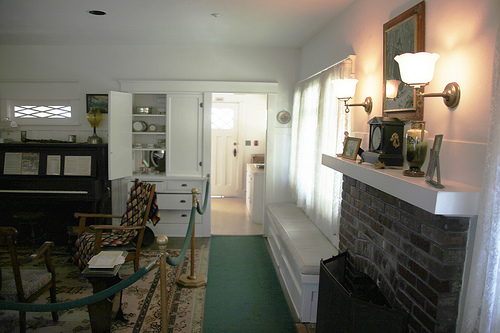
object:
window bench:
[264, 150, 368, 300]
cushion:
[266, 202, 354, 275]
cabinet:
[109, 85, 203, 237]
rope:
[168, 201, 196, 267]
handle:
[182, 184, 187, 187]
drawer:
[167, 181, 201, 191]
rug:
[3, 239, 210, 333]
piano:
[3, 137, 110, 250]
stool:
[0, 228, 62, 329]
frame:
[380, 2, 425, 136]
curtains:
[287, 60, 354, 237]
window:
[288, 61, 351, 236]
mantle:
[319, 152, 481, 215]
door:
[209, 102, 241, 198]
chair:
[75, 182, 156, 277]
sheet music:
[46, 155, 60, 176]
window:
[14, 105, 72, 119]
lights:
[330, 78, 372, 112]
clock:
[358, 116, 406, 169]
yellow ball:
[313, 162, 480, 323]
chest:
[258, 204, 337, 322]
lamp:
[394, 52, 462, 108]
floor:
[207, 198, 249, 231]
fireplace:
[319, 153, 477, 333]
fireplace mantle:
[321, 154, 484, 215]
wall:
[299, 0, 499, 185]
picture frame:
[425, 134, 446, 190]